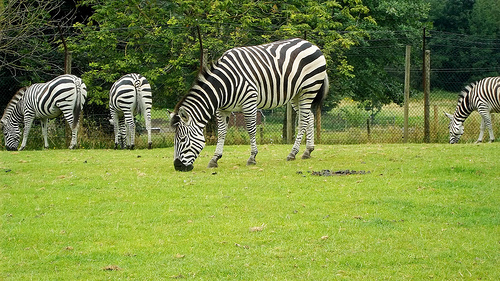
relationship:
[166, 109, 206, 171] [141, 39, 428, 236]
head of zebra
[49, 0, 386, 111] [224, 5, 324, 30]
tree with leaves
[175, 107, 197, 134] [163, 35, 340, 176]
ear of zebra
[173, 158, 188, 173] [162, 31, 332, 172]
nose of zebra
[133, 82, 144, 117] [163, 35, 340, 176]
tail of zebra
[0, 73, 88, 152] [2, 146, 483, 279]
zebra eating grass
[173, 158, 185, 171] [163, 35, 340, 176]
nose on zebra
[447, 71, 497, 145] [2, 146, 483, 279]
zebra eating grass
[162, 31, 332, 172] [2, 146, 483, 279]
zebra eating grass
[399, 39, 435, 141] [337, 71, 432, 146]
pole holding fence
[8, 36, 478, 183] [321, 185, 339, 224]
zebra eating grass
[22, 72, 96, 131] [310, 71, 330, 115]
zebra dangling tail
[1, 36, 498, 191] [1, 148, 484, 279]
zebras field in a field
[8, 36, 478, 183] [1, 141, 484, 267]
zebra standing in field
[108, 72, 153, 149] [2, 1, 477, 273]
zebra eating in field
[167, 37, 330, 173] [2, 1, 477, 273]
zebra eating in field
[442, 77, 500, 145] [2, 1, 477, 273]
zebra eating in field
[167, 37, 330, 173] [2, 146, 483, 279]
zebra eating grass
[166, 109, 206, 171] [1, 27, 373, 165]
head down on zebras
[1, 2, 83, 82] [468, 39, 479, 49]
tree with leaf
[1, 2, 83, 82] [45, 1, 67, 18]
tree with branch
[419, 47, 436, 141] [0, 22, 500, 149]
pole with fence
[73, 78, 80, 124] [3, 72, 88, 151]
tail of zebra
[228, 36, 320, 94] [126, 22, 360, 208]
stripes of zebra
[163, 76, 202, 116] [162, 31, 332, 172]
manes of zebra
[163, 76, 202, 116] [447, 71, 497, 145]
manes of zebra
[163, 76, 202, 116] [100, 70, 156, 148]
manes of zebra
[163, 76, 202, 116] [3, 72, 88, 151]
manes of zebra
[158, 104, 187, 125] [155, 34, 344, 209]
ears of zebra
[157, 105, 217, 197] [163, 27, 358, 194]
head of zebra